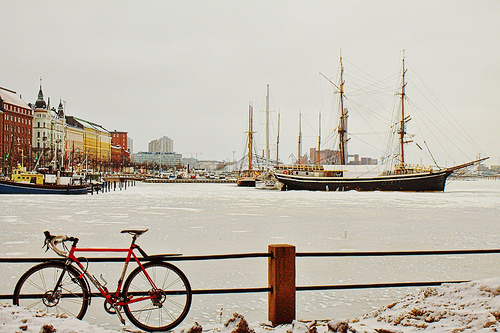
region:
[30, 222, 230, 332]
bike parked by the fence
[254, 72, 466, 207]
ship on the water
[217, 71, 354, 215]
ship on the water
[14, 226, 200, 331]
red bicycle leaning on fence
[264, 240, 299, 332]
thick brown wooden fence post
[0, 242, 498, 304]
black metal fence beams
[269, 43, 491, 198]
black ship docked near city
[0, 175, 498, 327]
snow covering frozen body of water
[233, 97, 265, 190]
ship docked near shore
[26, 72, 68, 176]
white building with spires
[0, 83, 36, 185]
square red brick building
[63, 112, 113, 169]
rectangular yellow building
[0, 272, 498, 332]
rocks covered with snow next to fence and body of water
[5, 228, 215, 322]
a bike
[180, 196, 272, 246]
the water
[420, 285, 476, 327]
snow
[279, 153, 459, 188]
a long boat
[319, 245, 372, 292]
poles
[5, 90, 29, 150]
a brown building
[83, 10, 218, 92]
the sky is clear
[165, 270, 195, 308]
the tire on the bike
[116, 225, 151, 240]
seat on the bike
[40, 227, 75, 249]
the handle bars on the bike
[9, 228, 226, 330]
Window of a bicycle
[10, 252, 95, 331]
Wheel of a bicycle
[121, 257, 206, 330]
Wheel of a bicycle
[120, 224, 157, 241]
Seat of a bicycle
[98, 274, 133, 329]
Pedals of a bicycle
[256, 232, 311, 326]
This is a pillar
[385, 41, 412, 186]
Center pillar of a boat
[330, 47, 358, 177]
Center pillar of a boat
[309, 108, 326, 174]
Center pillar of a boat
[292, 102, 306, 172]
Center pillar of a boat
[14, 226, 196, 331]
Bicycle parked near water.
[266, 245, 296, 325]
Wooden stake supporting fence cable.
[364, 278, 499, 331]
Rocks along riverside.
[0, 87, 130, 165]
Several buildings side by side.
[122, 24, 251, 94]
White hazy cloudless sky.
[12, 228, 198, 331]
Red bicycle parked along fence.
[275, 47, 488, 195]
Black boat with tall mast on water.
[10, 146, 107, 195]
Boats parked along pier.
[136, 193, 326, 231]
Cloudy calm waters of river.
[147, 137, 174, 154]
Tall building in background.